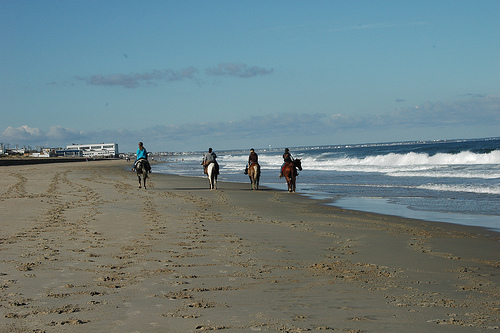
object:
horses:
[242, 162, 262, 191]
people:
[129, 141, 154, 174]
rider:
[198, 146, 223, 175]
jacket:
[134, 147, 148, 161]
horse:
[199, 157, 221, 190]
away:
[0, 1, 499, 161]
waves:
[182, 150, 500, 180]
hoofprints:
[171, 279, 190, 286]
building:
[64, 143, 119, 159]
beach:
[0, 155, 499, 333]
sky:
[0, 1, 500, 152]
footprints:
[191, 315, 234, 331]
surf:
[134, 136, 500, 231]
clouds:
[44, 61, 278, 91]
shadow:
[213, 186, 251, 192]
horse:
[279, 158, 301, 192]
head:
[291, 157, 304, 171]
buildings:
[48, 148, 86, 157]